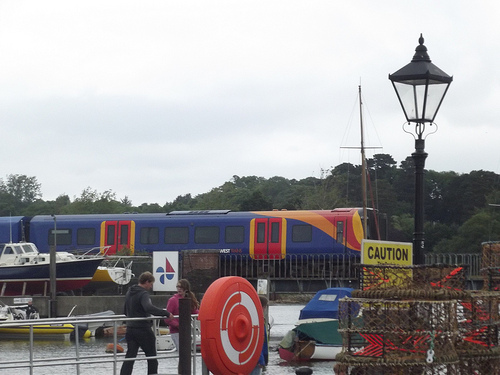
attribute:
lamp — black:
[387, 28, 457, 287]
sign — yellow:
[359, 234, 419, 265]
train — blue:
[5, 201, 390, 279]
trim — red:
[320, 208, 365, 254]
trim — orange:
[312, 206, 362, 253]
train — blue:
[0, 197, 400, 289]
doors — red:
[247, 214, 287, 264]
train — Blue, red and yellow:
[0, 207, 387, 256]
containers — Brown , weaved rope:
[333, 239, 497, 372]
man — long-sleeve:
[118, 270, 174, 372]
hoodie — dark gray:
[121, 283, 169, 327]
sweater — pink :
[164, 291, 200, 331]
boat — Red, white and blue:
[0, 239, 107, 293]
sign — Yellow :
[360, 238, 414, 293]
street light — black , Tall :
[387, 31, 454, 264]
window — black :
[46, 229, 72, 246]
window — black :
[76, 228, 96, 245]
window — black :
[105, 223, 115, 246]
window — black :
[117, 223, 127, 247]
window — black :
[137, 225, 157, 245]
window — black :
[163, 224, 188, 246]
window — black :
[193, 222, 221, 245]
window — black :
[224, 224, 247, 245]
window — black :
[251, 216, 267, 256]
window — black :
[272, 218, 283, 240]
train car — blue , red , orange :
[6, 212, 369, 267]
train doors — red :
[254, 219, 289, 253]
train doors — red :
[103, 219, 135, 261]